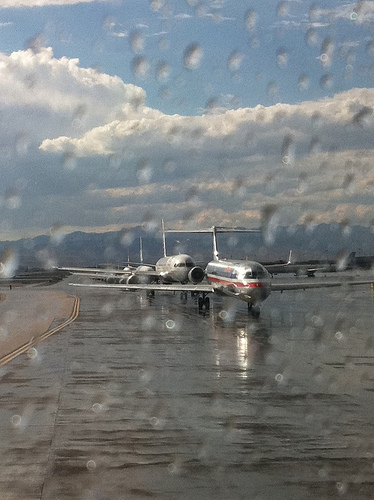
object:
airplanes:
[66, 231, 374, 322]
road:
[0, 266, 374, 498]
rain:
[1, 1, 374, 500]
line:
[52, 280, 216, 293]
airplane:
[53, 218, 196, 332]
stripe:
[205, 272, 265, 293]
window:
[246, 271, 268, 281]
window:
[2, 0, 374, 497]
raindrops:
[126, 35, 158, 88]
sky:
[1, 1, 374, 241]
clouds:
[0, 0, 374, 245]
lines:
[1, 290, 83, 367]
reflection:
[211, 319, 249, 380]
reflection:
[231, 265, 255, 282]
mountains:
[2, 224, 373, 267]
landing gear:
[196, 295, 263, 316]